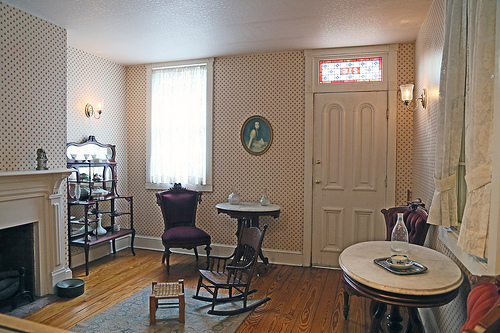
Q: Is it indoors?
A: Yes, it is indoors.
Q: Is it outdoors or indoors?
A: It is indoors.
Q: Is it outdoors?
A: No, it is indoors.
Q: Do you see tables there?
A: Yes, there is a table.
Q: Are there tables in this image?
A: Yes, there is a table.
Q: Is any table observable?
A: Yes, there is a table.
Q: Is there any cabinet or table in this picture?
A: Yes, there is a table.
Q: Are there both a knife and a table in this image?
A: No, there is a table but no knives.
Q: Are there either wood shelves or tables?
A: Yes, there is a wood table.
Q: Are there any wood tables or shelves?
A: Yes, there is a wood table.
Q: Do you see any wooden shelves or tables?
A: Yes, there is a wood table.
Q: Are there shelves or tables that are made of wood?
A: Yes, the table is made of wood.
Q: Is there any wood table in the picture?
A: Yes, there is a wood table.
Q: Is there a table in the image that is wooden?
A: Yes, there is a table that is wooden.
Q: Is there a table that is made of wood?
A: Yes, there is a table that is made of wood.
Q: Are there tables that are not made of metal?
A: Yes, there is a table that is made of wood.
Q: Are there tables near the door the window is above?
A: Yes, there is a table near the door.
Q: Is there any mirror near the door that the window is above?
A: No, there is a table near the door.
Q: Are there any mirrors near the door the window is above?
A: No, there is a table near the door.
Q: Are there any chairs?
A: Yes, there is a chair.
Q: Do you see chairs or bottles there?
A: Yes, there is a chair.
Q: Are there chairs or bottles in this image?
A: Yes, there is a chair.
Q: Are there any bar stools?
A: No, there are no bar stools.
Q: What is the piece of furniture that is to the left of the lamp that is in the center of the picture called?
A: The piece of furniture is a chair.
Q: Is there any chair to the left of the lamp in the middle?
A: Yes, there is a chair to the left of the lamp.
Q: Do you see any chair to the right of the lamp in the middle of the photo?
A: No, the chair is to the left of the lamp.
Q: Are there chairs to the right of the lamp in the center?
A: No, the chair is to the left of the lamp.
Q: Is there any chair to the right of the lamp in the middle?
A: No, the chair is to the left of the lamp.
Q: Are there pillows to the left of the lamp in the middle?
A: No, there is a chair to the left of the lamp.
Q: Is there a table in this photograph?
A: Yes, there is a table.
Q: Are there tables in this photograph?
A: Yes, there is a table.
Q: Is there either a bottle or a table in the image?
A: Yes, there is a table.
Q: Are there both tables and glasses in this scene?
A: Yes, there are both a table and glasses.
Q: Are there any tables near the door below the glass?
A: Yes, there is a table near the door.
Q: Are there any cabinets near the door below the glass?
A: No, there is a table near the door.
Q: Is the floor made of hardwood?
A: Yes, the floor is made of hardwood.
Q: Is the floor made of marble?
A: No, the floor is made of hardwood.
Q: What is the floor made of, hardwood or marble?
A: The floor is made of hardwood.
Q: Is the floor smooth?
A: Yes, the floor is smooth.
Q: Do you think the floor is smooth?
A: Yes, the floor is smooth.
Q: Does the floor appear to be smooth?
A: Yes, the floor is smooth.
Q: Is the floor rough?
A: No, the floor is smooth.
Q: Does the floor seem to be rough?
A: No, the floor is smooth.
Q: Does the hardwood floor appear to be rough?
A: No, the floor is smooth.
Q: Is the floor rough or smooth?
A: The floor is smooth.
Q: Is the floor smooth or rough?
A: The floor is smooth.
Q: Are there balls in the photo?
A: No, there are no balls.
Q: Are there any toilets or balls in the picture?
A: No, there are no balls or toilets.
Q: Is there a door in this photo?
A: Yes, there is a door.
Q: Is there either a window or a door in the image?
A: Yes, there is a door.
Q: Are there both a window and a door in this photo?
A: Yes, there are both a door and a window.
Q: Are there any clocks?
A: No, there are no clocks.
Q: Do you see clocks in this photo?
A: No, there are no clocks.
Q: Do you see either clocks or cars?
A: No, there are no clocks or cars.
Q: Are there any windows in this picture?
A: Yes, there is a window.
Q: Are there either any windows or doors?
A: Yes, there is a window.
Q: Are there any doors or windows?
A: Yes, there is a window.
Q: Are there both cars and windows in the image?
A: No, there is a window but no cars.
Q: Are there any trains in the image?
A: No, there are no trains.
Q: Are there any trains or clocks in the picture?
A: No, there are no trains or clocks.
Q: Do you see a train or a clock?
A: No, there are no trains or clocks.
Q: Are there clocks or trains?
A: No, there are no trains or clocks.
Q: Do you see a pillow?
A: No, there are no pillows.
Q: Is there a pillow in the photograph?
A: No, there are no pillows.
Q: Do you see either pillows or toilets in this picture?
A: No, there are no pillows or toilets.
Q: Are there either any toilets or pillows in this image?
A: No, there are no pillows or toilets.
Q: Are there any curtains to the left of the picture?
A: Yes, there is a curtain to the left of the picture.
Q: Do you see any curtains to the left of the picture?
A: Yes, there is a curtain to the left of the picture.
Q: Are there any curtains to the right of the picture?
A: No, the curtain is to the left of the picture.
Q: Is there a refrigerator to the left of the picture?
A: No, there is a curtain to the left of the picture.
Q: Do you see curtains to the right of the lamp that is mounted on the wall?
A: Yes, there is a curtain to the right of the lamp.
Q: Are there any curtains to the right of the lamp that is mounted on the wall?
A: Yes, there is a curtain to the right of the lamp.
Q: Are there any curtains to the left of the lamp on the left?
A: No, the curtain is to the right of the lamp.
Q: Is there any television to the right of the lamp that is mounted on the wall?
A: No, there is a curtain to the right of the lamp.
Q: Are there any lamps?
A: Yes, there is a lamp.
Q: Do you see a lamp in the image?
A: Yes, there is a lamp.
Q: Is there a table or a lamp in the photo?
A: Yes, there is a lamp.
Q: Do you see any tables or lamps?
A: Yes, there is a lamp.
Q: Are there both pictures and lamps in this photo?
A: Yes, there are both a lamp and a picture.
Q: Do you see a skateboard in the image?
A: No, there are no skateboards.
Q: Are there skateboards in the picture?
A: No, there are no skateboards.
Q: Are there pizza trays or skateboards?
A: No, there are no skateboards or pizza trays.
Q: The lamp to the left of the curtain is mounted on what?
A: The lamp is mounted on the wall.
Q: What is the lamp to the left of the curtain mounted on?
A: The lamp is mounted on the wall.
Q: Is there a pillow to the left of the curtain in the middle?
A: No, there is a lamp to the left of the curtain.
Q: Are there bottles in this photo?
A: Yes, there is a bottle.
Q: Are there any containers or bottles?
A: Yes, there is a bottle.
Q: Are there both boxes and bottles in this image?
A: No, there is a bottle but no boxes.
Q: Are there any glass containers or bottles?
A: Yes, there is a glass bottle.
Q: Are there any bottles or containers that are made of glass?
A: Yes, the bottle is made of glass.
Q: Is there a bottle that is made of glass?
A: Yes, there is a bottle that is made of glass.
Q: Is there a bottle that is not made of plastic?
A: Yes, there is a bottle that is made of glass.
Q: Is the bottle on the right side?
A: Yes, the bottle is on the right of the image.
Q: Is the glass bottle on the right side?
A: Yes, the bottle is on the right of the image.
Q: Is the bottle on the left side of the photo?
A: No, the bottle is on the right of the image.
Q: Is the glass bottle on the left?
A: No, the bottle is on the right of the image.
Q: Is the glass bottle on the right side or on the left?
A: The bottle is on the right of the image.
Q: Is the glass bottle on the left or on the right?
A: The bottle is on the right of the image.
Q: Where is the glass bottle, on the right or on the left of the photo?
A: The bottle is on the right of the image.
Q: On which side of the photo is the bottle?
A: The bottle is on the right of the image.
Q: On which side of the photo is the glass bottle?
A: The bottle is on the right of the image.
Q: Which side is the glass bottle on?
A: The bottle is on the right of the image.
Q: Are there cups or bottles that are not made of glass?
A: No, there is a bottle but it is made of glass.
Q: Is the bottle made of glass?
A: Yes, the bottle is made of glass.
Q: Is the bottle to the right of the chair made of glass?
A: Yes, the bottle is made of glass.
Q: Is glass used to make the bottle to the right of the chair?
A: Yes, the bottle is made of glass.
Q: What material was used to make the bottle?
A: The bottle is made of glass.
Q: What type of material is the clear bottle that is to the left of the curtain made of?
A: The bottle is made of glass.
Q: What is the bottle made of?
A: The bottle is made of glass.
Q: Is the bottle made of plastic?
A: No, the bottle is made of glass.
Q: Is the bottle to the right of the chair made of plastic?
A: No, the bottle is made of glass.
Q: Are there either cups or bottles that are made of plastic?
A: No, there is a bottle but it is made of glass.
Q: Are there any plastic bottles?
A: No, there is a bottle but it is made of glass.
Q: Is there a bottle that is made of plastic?
A: No, there is a bottle but it is made of glass.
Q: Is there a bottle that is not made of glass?
A: No, there is a bottle but it is made of glass.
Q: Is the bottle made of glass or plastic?
A: The bottle is made of glass.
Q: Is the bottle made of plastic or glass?
A: The bottle is made of glass.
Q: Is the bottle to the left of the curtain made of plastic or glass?
A: The bottle is made of glass.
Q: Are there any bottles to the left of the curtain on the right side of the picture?
A: Yes, there is a bottle to the left of the curtain.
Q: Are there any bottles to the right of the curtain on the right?
A: No, the bottle is to the left of the curtain.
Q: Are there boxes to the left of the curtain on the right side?
A: No, there is a bottle to the left of the curtain.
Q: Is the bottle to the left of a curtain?
A: Yes, the bottle is to the left of a curtain.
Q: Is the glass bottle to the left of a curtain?
A: Yes, the bottle is to the left of a curtain.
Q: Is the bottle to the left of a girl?
A: No, the bottle is to the left of a curtain.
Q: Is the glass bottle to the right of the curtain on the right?
A: No, the bottle is to the left of the curtain.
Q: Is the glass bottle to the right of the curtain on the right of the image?
A: No, the bottle is to the left of the curtain.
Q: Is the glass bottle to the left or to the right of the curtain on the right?
A: The bottle is to the left of the curtain.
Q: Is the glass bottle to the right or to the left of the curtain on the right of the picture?
A: The bottle is to the left of the curtain.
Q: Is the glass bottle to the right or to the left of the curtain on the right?
A: The bottle is to the left of the curtain.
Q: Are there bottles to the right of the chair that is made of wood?
A: Yes, there is a bottle to the right of the chair.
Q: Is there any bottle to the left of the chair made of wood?
A: No, the bottle is to the right of the chair.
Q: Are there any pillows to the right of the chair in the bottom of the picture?
A: No, there is a bottle to the right of the chair.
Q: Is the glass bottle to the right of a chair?
A: Yes, the bottle is to the right of a chair.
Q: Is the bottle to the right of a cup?
A: No, the bottle is to the right of a chair.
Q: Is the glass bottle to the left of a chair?
A: No, the bottle is to the right of a chair.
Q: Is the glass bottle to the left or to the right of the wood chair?
A: The bottle is to the right of the chair.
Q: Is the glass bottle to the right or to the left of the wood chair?
A: The bottle is to the right of the chair.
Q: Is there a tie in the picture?
A: Yes, there is a tie.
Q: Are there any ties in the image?
A: Yes, there is a tie.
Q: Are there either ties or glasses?
A: Yes, there is a tie.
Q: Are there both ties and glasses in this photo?
A: Yes, there are both a tie and glasses.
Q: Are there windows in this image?
A: Yes, there is a window.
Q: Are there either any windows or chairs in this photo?
A: Yes, there is a window.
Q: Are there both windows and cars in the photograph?
A: No, there is a window but no cars.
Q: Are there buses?
A: No, there are no buses.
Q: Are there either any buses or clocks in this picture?
A: No, there are no buses or clocks.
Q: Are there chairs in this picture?
A: Yes, there is a chair.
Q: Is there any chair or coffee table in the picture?
A: Yes, there is a chair.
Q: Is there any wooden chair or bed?
A: Yes, there is a wood chair.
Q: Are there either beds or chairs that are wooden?
A: Yes, the chair is wooden.